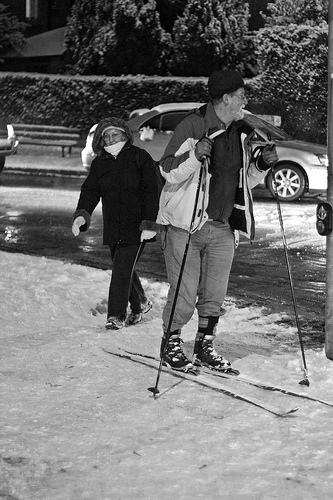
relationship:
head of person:
[98, 121, 125, 154] [70, 111, 185, 293]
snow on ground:
[0, 253, 333, 499] [5, 239, 331, 494]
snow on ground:
[0, 253, 328, 499] [4, 171, 332, 498]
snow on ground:
[0, 253, 333, 499] [4, 137, 329, 499]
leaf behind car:
[287, 80, 316, 97] [80, 102, 326, 199]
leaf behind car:
[288, 100, 307, 110] [83, 92, 332, 197]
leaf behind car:
[289, 93, 295, 97] [80, 102, 326, 199]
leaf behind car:
[307, 71, 313, 83] [80, 102, 326, 199]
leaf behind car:
[267, 33, 279, 45] [80, 102, 326, 199]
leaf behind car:
[253, 98, 258, 101] [80, 102, 326, 199]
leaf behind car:
[310, 32, 324, 45] [80, 102, 326, 199]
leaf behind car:
[264, 15, 275, 25] [80, 102, 326, 199]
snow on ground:
[0, 253, 333, 499] [247, 252, 284, 303]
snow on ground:
[259, 307, 299, 349] [10, 250, 324, 467]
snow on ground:
[0, 253, 333, 499] [25, 297, 129, 352]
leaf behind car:
[293, 70, 306, 85] [80, 102, 326, 199]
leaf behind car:
[306, 60, 316, 71] [271, 131, 323, 195]